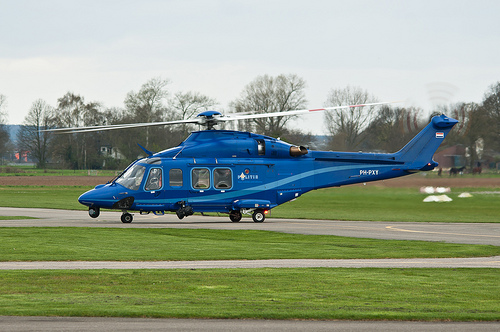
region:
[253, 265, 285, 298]
part of a green grass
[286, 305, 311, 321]
edge of the field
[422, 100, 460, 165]
tail wing of the plane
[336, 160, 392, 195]
edge of the plane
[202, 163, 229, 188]
part of a window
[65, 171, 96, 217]
tip of the plane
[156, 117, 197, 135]
edge of a propellor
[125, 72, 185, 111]
part of some leaves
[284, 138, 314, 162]
part of an exhaust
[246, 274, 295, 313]
part of some green grass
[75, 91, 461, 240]
blue helicopter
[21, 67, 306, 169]
trees with sparse foliage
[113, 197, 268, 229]
helicopter landing gear tires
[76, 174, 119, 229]
metal pointed nose of helicopter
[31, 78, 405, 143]
helicopter rotors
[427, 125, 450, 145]
small red, white, and blue decal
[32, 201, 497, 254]
asphalt helicopter landing area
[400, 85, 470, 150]
helicopter tail rotor in motion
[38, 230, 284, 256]
short cut green grass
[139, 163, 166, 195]
pilot's window on helicopter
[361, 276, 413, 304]
section of grass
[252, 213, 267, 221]
wheels of a helicopter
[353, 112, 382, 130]
branches of a tree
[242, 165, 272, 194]
blue part of a helicopter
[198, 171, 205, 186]
window of an helicopter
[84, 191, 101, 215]
front part of an helicopter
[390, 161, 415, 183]
back part of an helicopter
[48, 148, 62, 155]
group of trees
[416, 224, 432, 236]
section of a run way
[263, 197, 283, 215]
bottom part of a helicopter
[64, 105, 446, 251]
The plane is blue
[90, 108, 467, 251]
Plane sitting on runway.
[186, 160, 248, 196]
Helicopter has windows.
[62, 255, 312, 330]
The grass is green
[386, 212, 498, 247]
A yellow line in middle of runway.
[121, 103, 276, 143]
Propeller on top of helicopter.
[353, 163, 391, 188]
The writing is white.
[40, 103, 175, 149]
Trees sit next to the runway.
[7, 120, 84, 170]
A building sit in the background.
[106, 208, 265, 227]
Wheel on the helicopter.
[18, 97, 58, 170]
a tree in a distance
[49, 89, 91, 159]
a tree in a distance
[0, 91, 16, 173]
a tree in a distance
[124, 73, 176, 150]
a tree in a distance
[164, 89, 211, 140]
a tree in a distance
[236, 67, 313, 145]
a tree in a distance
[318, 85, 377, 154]
a tree in a distance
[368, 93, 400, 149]
a tree in a distance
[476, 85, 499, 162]
a tree in a distance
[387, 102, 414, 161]
a tree in a distance